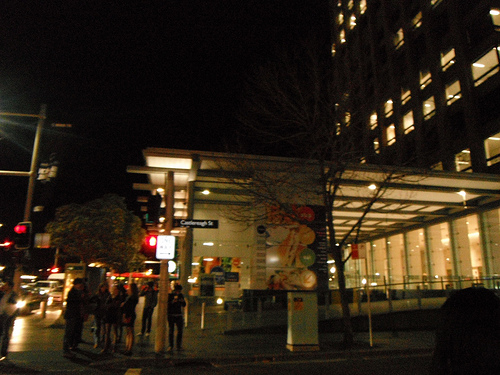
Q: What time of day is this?
A: Evening.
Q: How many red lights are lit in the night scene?
A: Two.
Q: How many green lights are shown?
A: 1.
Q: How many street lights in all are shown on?
A: 5.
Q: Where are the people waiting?
A: Street corner.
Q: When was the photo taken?
A: Nightime.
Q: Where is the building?
A: Right of the people.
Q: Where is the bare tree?
A: In front of the shorter building.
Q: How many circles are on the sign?
A: 4.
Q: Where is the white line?
A: On the road.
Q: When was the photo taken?
A: Night.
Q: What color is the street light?
A: Red.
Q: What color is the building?
A: White.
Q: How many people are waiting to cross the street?
A: Eight.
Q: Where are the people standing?
A: Other side.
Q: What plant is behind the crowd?
A: Tree.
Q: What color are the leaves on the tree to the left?
A: Green.